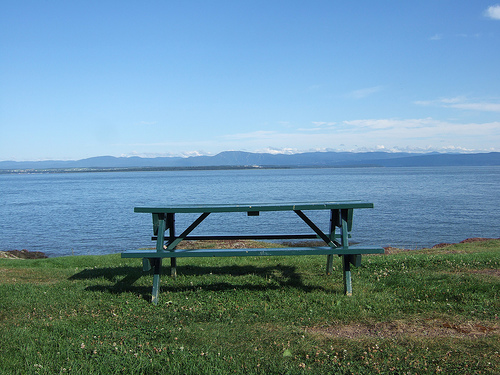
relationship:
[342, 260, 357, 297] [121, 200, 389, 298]
leg of bench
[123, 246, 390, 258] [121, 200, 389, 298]
seat of a bench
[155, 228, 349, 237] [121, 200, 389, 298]
seat of a bench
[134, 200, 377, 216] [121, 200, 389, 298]
top of bench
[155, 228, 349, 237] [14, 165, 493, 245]
seat near water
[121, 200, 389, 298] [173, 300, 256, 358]
bench on top of grass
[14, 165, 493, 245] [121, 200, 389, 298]
water between bench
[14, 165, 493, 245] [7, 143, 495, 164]
water between mountain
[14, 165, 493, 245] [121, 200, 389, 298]
water beside bench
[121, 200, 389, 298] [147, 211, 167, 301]
bench has leg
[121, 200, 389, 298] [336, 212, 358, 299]
bench has leg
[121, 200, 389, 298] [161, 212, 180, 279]
bench has leg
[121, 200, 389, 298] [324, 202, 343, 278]
bench has leg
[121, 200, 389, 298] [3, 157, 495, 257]
bench away from water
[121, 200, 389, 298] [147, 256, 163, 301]
bench has feet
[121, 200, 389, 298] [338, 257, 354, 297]
bench has feet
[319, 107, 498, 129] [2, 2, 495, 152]
cloud in sky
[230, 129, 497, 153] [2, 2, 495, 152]
cloud in sky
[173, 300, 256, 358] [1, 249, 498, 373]
grass on ground